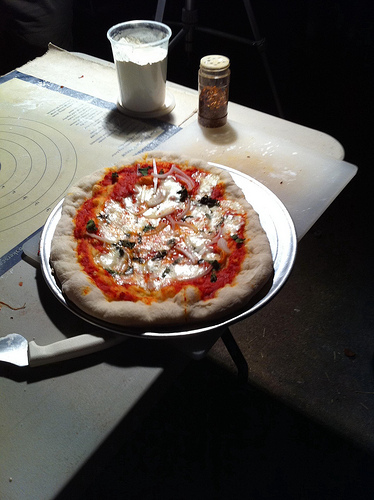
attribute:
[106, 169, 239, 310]
pizza — red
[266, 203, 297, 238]
plate — brown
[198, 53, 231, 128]
bottle — brown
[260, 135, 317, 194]
table — brown